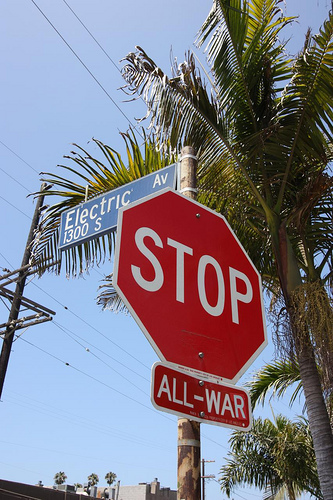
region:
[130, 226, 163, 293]
White S on a stop sign.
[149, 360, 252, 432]
Sign under the stop sign that says ALL-WAR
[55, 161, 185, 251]
Blue sign that says Electric Ave 1300 S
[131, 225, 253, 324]
The word STOP on the sign.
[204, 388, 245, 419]
The word WAR in white letters.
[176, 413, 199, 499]
Pole that has signs attached to it.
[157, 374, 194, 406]
The word ALL in white letters.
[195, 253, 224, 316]
The letter O on a stop sign.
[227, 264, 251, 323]
The letter P on a stop sign.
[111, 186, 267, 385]
Octagon shaped stop sign.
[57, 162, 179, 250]
sign for street identification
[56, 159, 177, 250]
a street sign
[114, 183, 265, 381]
a red and white sign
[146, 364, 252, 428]
a red and white sign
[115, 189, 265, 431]
a pacifist message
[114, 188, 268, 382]
a sign with a light border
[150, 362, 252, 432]
a sign with a light border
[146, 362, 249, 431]
a sign with white lettering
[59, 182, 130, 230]
the word "electric"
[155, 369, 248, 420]
"ALL-WAR" text on signpost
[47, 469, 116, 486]
Three palm trees in the background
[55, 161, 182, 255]
A street name that says "Electric Ave"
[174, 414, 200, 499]
A rusty metal sign post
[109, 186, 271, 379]
A red hexagonal stop sign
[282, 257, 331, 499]
A palm tree trunk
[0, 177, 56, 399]
An electric post with may cables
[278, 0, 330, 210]
A palm tree's leaf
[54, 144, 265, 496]
An red stop sign coupled with a street name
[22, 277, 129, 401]
Electric cables hanging from a post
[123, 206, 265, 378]
the sign is red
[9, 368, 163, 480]
the sky is blue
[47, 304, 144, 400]
electric wires are black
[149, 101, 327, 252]
the trees are palm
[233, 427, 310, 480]
the leaves are green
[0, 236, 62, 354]
wires are attached to post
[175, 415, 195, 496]
stop sign is on post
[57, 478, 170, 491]
buildings are in background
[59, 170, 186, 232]
street sign is blue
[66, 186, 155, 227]
street name is Electric Avenue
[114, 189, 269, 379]
a stop sign attached to the pole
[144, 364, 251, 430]
a sign altered to say 'all war'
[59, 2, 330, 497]
some palm trees on the side of the road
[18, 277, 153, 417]
power lines behind the stop sign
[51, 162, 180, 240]
a street sign saying the name of the street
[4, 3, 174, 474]
the sunny blue sky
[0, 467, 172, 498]
assorted buildings on the side of the road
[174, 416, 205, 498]
a pole for the signs to hang on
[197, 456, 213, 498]
a power pole next to the building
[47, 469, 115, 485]
even more palm trees